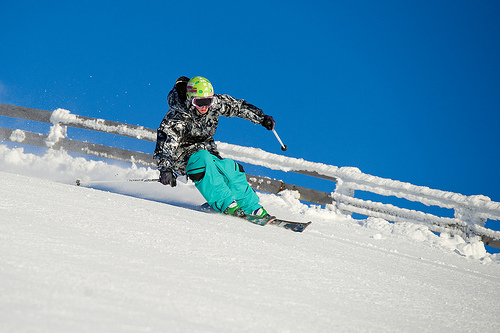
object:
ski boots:
[200, 201, 311, 233]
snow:
[0, 145, 498, 331]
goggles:
[190, 97, 214, 108]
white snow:
[0, 106, 499, 331]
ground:
[0, 147, 498, 331]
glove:
[263, 115, 276, 131]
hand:
[258, 114, 277, 131]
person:
[151, 75, 276, 227]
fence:
[0, 104, 499, 251]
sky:
[0, 0, 499, 254]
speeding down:
[198, 199, 310, 233]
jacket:
[150, 77, 262, 175]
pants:
[184, 150, 262, 217]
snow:
[0, 103, 499, 248]